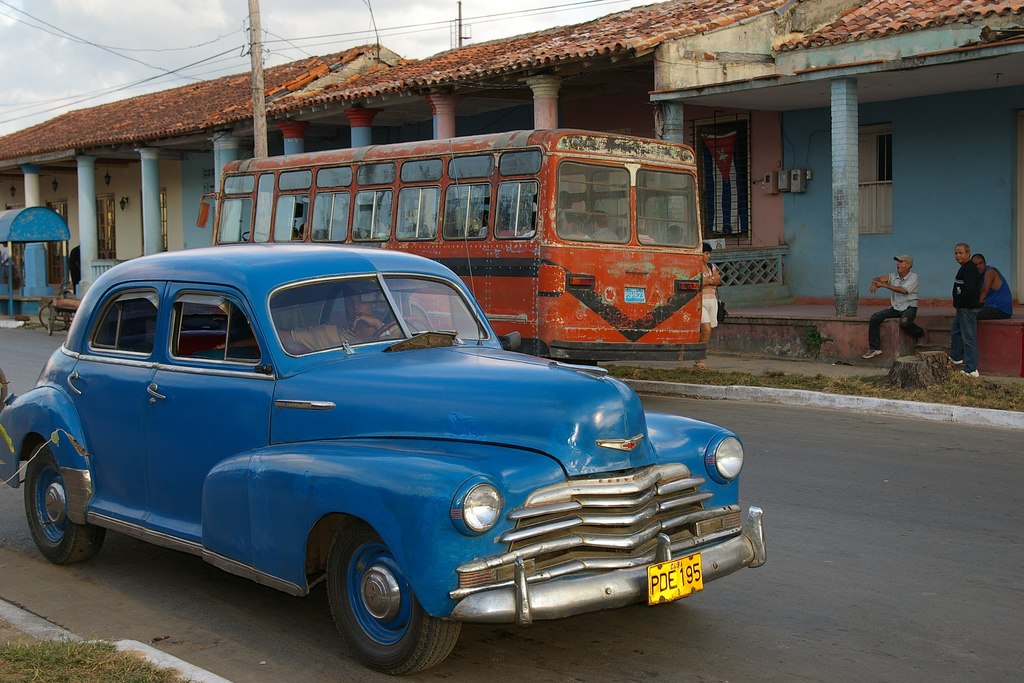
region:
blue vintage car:
[2, 233, 775, 680]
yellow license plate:
[634, 543, 714, 610]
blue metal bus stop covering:
[0, 196, 80, 330]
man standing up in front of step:
[945, 233, 993, 382]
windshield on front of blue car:
[262, 268, 493, 361]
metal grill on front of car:
[436, 458, 746, 596]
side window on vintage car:
[164, 285, 264, 369]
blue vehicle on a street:
[6, 222, 787, 678]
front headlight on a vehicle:
[447, 472, 505, 536]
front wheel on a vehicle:
[307, 497, 466, 672]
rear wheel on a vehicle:
[11, 419, 106, 566]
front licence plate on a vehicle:
[634, 536, 705, 601]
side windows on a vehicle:
[79, 277, 279, 375]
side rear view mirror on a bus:
[186, 186, 226, 232]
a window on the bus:
[590, 159, 628, 232]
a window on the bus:
[629, 145, 684, 259]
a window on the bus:
[465, 145, 488, 247]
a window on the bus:
[403, 130, 438, 223]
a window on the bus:
[333, 171, 391, 244]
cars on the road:
[34, 165, 781, 662]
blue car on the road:
[87, 203, 816, 674]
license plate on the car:
[571, 503, 822, 677]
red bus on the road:
[223, 116, 1015, 379]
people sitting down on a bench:
[818, 158, 1018, 414]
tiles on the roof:
[34, 34, 544, 230]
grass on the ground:
[34, 585, 272, 674]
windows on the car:
[69, 275, 535, 450]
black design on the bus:
[527, 198, 810, 405]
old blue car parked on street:
[2, 241, 771, 674]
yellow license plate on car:
[641, 550, 705, 599]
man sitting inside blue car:
[219, 286, 413, 359]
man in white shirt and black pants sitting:
[856, 253, 929, 362]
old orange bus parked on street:
[212, 125, 702, 360]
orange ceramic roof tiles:
[4, 3, 1022, 160]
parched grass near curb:
[2, 611, 198, 679]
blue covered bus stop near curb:
[2, 206, 70, 334]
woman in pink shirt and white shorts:
[698, 235, 719, 354]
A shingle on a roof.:
[593, 30, 616, 47]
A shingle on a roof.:
[591, 35, 602, 43]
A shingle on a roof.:
[544, 30, 555, 38]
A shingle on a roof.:
[515, 40, 542, 59]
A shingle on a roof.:
[479, 52, 490, 66]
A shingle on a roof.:
[411, 59, 434, 80]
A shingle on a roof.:
[359, 76, 369, 81]